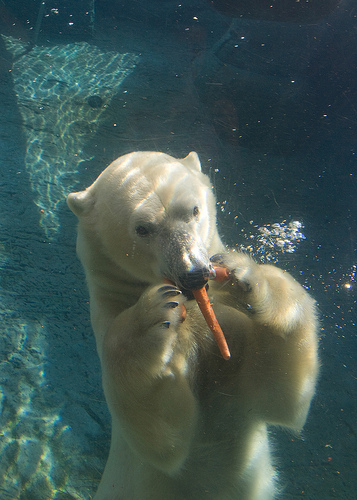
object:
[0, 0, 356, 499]
water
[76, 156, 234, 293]
face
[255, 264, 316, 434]
arm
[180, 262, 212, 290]
nose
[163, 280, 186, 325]
carrot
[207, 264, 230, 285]
carrot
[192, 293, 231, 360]
carrot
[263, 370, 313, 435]
elbow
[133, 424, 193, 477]
elbow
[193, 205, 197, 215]
eye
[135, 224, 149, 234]
eye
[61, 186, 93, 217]
bear ear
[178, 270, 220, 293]
mouth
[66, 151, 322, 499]
bear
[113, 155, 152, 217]
fur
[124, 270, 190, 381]
paw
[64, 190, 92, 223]
ear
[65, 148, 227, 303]
head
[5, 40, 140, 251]
reflection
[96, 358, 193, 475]
right arm